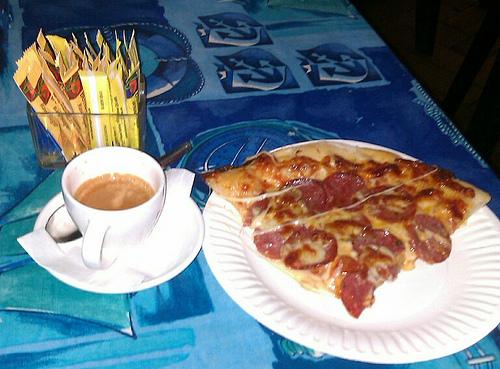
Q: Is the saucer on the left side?
A: Yes, the saucer is on the left of the image.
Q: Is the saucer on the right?
A: No, the saucer is on the left of the image.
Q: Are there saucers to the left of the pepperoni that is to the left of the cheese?
A: Yes, there is a saucer to the left of the pepperoni.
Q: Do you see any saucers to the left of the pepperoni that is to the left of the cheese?
A: Yes, there is a saucer to the left of the pepperoni.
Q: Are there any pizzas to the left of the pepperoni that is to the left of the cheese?
A: No, there is a saucer to the left of the pepperoni.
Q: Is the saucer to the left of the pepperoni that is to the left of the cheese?
A: Yes, the saucer is to the left of the pepperoni.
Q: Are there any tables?
A: Yes, there is a table.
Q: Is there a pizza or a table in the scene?
A: Yes, there is a table.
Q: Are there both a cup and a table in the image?
A: Yes, there are both a table and a cup.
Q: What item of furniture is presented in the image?
A: The piece of furniture is a table.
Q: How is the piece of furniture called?
A: The piece of furniture is a table.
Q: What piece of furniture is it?
A: The piece of furniture is a table.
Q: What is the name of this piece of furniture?
A: That is a table.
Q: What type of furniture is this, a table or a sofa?
A: That is a table.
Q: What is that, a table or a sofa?
A: That is a table.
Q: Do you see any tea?
A: Yes, there is tea.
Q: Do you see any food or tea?
A: Yes, there is tea.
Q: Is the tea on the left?
A: Yes, the tea is on the left of the image.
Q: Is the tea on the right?
A: No, the tea is on the left of the image.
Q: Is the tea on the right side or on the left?
A: The tea is on the left of the image.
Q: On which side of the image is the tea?
A: The tea is on the left of the image.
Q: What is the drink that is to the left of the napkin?
A: The drink is tea.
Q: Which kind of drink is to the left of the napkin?
A: The drink is tea.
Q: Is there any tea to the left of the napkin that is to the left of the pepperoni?
A: Yes, there is tea to the left of the napkin.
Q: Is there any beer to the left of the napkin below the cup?
A: No, there is tea to the left of the napkin.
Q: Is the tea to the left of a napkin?
A: Yes, the tea is to the left of a napkin.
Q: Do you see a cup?
A: Yes, there is a cup.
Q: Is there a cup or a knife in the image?
A: Yes, there is a cup.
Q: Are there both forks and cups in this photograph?
A: No, there is a cup but no forks.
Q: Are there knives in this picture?
A: No, there are no knives.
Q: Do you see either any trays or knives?
A: No, there are no knives or trays.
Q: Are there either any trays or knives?
A: No, there are no knives or trays.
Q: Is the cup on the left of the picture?
A: Yes, the cup is on the left of the image.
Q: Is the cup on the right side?
A: No, the cup is on the left of the image.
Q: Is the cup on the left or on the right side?
A: The cup is on the left of the image.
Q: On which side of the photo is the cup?
A: The cup is on the left of the image.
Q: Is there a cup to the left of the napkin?
A: Yes, there is a cup to the left of the napkin.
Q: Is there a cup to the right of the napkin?
A: No, the cup is to the left of the napkin.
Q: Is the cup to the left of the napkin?
A: Yes, the cup is to the left of the napkin.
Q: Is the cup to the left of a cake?
A: No, the cup is to the left of the napkin.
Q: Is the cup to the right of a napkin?
A: No, the cup is to the left of a napkin.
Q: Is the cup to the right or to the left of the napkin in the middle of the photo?
A: The cup is to the left of the napkin.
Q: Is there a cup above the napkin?
A: Yes, there is a cup above the napkin.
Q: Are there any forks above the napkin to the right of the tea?
A: No, there is a cup above the napkin.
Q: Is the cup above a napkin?
A: Yes, the cup is above a napkin.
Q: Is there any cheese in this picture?
A: Yes, there is cheese.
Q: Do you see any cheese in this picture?
A: Yes, there is cheese.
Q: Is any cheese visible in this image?
A: Yes, there is cheese.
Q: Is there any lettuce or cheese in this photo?
A: Yes, there is cheese.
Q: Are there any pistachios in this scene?
A: No, there are no pistachios.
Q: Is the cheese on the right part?
A: Yes, the cheese is on the right of the image.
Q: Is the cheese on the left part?
A: No, the cheese is on the right of the image.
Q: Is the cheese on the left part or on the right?
A: The cheese is on the right of the image.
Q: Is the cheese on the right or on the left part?
A: The cheese is on the right of the image.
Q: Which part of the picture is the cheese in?
A: The cheese is on the right of the image.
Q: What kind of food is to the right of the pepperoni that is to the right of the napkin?
A: The food is cheese.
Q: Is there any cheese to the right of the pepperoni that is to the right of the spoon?
A: Yes, there is cheese to the right of the pepperoni.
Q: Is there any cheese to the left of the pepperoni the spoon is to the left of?
A: No, the cheese is to the right of the pepperoni.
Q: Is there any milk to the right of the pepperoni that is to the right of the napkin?
A: No, there is cheese to the right of the pepperoni.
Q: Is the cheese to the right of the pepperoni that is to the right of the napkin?
A: Yes, the cheese is to the right of the pepperoni.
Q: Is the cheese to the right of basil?
A: No, the cheese is to the right of the pepperoni.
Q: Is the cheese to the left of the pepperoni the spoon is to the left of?
A: No, the cheese is to the right of the pepperoni.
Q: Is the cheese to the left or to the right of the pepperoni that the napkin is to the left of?
A: The cheese is to the right of the pepperoni.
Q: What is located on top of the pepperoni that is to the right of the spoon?
A: The cheese is on top of the pepperoni.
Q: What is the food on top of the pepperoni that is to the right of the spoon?
A: The food is cheese.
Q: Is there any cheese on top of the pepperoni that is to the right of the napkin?
A: Yes, there is cheese on top of the pepperoni.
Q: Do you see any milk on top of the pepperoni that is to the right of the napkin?
A: No, there is cheese on top of the pepperoni.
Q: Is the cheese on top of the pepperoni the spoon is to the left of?
A: Yes, the cheese is on top of the pepperoni.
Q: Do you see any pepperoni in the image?
A: Yes, there is pepperoni.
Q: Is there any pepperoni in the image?
A: Yes, there is pepperoni.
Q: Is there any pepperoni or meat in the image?
A: Yes, there is pepperoni.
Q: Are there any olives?
A: No, there are no olives.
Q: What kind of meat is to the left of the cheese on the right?
A: The meat is pepperoni.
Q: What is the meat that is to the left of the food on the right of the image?
A: The meat is pepperoni.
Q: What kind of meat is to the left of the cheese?
A: The meat is pepperoni.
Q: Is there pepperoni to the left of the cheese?
A: Yes, there is pepperoni to the left of the cheese.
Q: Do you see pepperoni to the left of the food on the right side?
A: Yes, there is pepperoni to the left of the cheese.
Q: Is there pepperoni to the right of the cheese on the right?
A: No, the pepperoni is to the left of the cheese.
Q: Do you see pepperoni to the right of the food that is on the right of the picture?
A: No, the pepperoni is to the left of the cheese.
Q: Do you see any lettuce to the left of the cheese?
A: No, there is pepperoni to the left of the cheese.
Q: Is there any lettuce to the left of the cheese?
A: No, there is pepperoni to the left of the cheese.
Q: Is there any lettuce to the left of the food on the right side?
A: No, there is pepperoni to the left of the cheese.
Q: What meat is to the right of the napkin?
A: The meat is pepperoni.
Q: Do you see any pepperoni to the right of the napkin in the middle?
A: Yes, there is pepperoni to the right of the napkin.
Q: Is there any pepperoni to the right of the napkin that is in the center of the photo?
A: Yes, there is pepperoni to the right of the napkin.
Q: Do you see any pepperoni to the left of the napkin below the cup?
A: No, the pepperoni is to the right of the napkin.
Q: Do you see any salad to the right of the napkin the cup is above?
A: No, there is pepperoni to the right of the napkin.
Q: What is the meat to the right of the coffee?
A: The meat is pepperoni.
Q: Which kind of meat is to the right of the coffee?
A: The meat is pepperoni.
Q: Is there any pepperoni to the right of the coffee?
A: Yes, there is pepperoni to the right of the coffee.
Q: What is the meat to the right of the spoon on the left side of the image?
A: The meat is pepperoni.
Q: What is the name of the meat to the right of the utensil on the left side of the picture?
A: The meat is pepperoni.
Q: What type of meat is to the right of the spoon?
A: The meat is pepperoni.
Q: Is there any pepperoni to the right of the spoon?
A: Yes, there is pepperoni to the right of the spoon.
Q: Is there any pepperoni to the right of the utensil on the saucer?
A: Yes, there is pepperoni to the right of the spoon.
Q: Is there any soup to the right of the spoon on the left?
A: No, there is pepperoni to the right of the spoon.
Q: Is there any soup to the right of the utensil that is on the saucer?
A: No, there is pepperoni to the right of the spoon.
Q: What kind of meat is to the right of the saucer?
A: The meat is pepperoni.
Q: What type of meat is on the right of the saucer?
A: The meat is pepperoni.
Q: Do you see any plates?
A: Yes, there is a plate.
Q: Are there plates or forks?
A: Yes, there is a plate.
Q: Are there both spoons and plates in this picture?
A: Yes, there are both a plate and a spoon.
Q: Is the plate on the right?
A: Yes, the plate is on the right of the image.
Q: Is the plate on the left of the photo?
A: No, the plate is on the right of the image.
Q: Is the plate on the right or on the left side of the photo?
A: The plate is on the right of the image.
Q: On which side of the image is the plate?
A: The plate is on the right of the image.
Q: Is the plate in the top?
A: No, the plate is in the bottom of the image.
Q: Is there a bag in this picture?
A: No, there are no bags.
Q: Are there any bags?
A: No, there are no bags.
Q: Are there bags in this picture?
A: No, there are no bags.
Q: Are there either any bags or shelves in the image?
A: No, there are no bags or shelves.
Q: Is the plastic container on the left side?
A: Yes, the container is on the left of the image.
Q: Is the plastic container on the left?
A: Yes, the container is on the left of the image.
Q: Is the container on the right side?
A: No, the container is on the left of the image.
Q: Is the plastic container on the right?
A: No, the container is on the left of the image.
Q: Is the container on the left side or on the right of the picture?
A: The container is on the left of the image.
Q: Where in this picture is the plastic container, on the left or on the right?
A: The container is on the left of the image.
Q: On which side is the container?
A: The container is on the left of the image.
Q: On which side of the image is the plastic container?
A: The container is on the left of the image.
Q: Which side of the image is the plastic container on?
A: The container is on the left of the image.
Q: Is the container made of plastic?
A: Yes, the container is made of plastic.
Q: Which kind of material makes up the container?
A: The container is made of plastic.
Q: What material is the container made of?
A: The container is made of plastic.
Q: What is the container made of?
A: The container is made of plastic.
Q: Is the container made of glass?
A: No, the container is made of plastic.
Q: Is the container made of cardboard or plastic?
A: The container is made of plastic.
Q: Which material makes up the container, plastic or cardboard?
A: The container is made of plastic.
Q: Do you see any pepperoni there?
A: Yes, there is pepperoni.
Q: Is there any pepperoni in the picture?
A: Yes, there is pepperoni.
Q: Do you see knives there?
A: No, there are no knives.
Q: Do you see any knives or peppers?
A: No, there are no knives or peppers.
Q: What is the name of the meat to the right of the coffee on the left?
A: The meat is pepperoni.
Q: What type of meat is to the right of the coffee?
A: The meat is pepperoni.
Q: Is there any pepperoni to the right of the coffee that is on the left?
A: Yes, there is pepperoni to the right of the coffee.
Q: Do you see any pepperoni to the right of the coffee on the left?
A: Yes, there is pepperoni to the right of the coffee.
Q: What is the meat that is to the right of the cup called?
A: The meat is pepperoni.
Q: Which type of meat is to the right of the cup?
A: The meat is pepperoni.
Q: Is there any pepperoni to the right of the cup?
A: Yes, there is pepperoni to the right of the cup.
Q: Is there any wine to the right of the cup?
A: No, there is pepperoni to the right of the cup.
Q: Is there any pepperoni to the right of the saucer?
A: Yes, there is pepperoni to the right of the saucer.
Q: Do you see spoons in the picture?
A: Yes, there is a spoon.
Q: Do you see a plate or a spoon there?
A: Yes, there is a spoon.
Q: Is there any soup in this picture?
A: No, there is no soup.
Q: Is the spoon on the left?
A: Yes, the spoon is on the left of the image.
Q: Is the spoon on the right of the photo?
A: No, the spoon is on the left of the image.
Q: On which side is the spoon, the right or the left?
A: The spoon is on the left of the image.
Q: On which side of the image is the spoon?
A: The spoon is on the left of the image.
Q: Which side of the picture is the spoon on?
A: The spoon is on the left of the image.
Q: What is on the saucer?
A: The spoon is on the saucer.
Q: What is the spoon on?
A: The spoon is on the saucer.